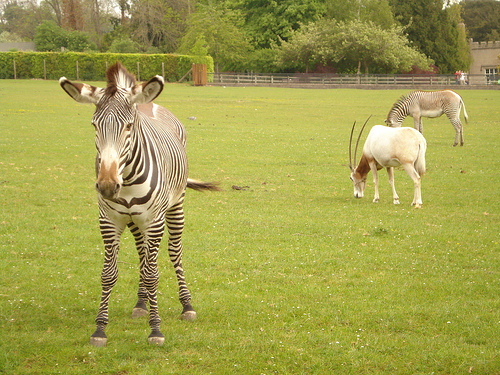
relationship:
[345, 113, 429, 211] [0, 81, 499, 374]
animal eating grass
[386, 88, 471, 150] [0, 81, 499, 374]
zebra eating grass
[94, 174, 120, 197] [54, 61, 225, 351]
snout on zebra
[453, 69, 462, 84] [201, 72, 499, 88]
person standing behind fence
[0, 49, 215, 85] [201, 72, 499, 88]
hedge making up fence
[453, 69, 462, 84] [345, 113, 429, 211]
person observing animal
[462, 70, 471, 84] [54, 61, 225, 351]
person observing zebra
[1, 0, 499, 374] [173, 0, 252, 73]
wooded area with tree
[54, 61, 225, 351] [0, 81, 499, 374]
zebra in grass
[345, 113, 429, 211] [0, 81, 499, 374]
animal in grass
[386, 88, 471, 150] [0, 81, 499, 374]
zebra in grass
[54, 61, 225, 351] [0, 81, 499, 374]
zebra standing on grass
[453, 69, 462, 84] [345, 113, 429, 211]
person looking at animal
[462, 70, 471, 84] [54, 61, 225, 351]
person looking at zebra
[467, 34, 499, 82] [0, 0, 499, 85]
building in background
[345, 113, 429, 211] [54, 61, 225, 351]
antelope with zebra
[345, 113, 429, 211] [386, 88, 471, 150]
antelope with zebra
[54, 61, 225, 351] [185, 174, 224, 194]
zebra wagging tail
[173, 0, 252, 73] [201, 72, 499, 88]
tree behind fence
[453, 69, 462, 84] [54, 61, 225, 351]
person seeing zebra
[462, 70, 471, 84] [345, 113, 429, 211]
person seeing animal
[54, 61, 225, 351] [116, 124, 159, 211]
zebra showing stripe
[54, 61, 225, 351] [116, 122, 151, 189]
zebra showing stripe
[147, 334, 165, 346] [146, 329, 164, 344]
dirt from hoofs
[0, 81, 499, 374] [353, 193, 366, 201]
grass for grazing